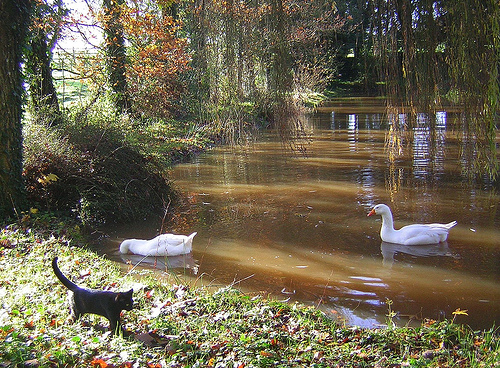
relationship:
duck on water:
[360, 194, 467, 258] [282, 153, 369, 203]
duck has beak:
[360, 194, 467, 258] [367, 207, 377, 216]